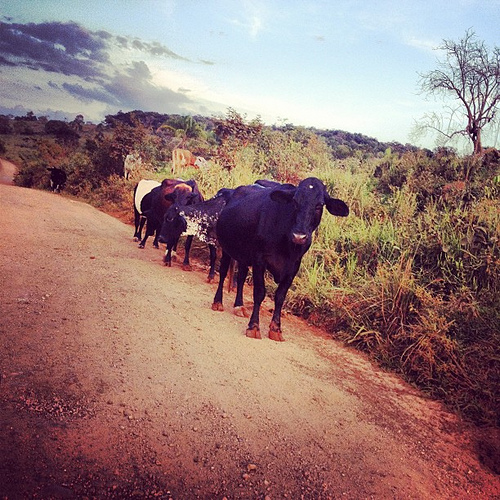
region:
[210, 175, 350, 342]
a black cow standing before other cows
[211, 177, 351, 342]
a black cow standing on the side of a dirt road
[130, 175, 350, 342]
four cows standing on the left side of the road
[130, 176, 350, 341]
cows standing on the side of the road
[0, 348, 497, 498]
the left side of a road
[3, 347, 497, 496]
a dirt road in the country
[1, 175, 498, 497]
four domestic cows on a dirt road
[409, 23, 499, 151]
a leafless brown tree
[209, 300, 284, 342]
hooves on the black cow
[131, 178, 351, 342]
cows on the side of a country road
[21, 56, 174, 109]
clouds in the sky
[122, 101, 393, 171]
trees and bushes in the background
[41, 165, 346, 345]
cows walking on the street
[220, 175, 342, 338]
a large black cow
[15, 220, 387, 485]
a dirt road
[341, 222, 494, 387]
grass next to the road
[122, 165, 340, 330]
a line of cows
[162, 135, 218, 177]
a brown cow in the grass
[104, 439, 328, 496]
rocks on the road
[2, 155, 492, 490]
dirt road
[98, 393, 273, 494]
small rocks in the road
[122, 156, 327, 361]
cows walking on the side of the road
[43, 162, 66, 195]
one cow trailing behind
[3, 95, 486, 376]
grass and trees on the side of the road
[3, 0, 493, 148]
blue sky with clouds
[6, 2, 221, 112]
dark grey clouds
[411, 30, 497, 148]
tree with no leaves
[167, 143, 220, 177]
a cow in the grass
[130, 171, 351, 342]
Cow on dirt road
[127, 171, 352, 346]
Cow on dirt road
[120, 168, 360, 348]
Cow on dirt road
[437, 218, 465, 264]
green grass on the hill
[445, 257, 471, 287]
green grass on the hill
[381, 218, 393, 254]
green grass on the hill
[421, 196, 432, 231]
green grass on the hill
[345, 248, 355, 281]
green grass on the hill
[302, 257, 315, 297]
green grass on the hill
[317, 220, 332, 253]
green grass on the hill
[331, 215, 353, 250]
green grass on the hill